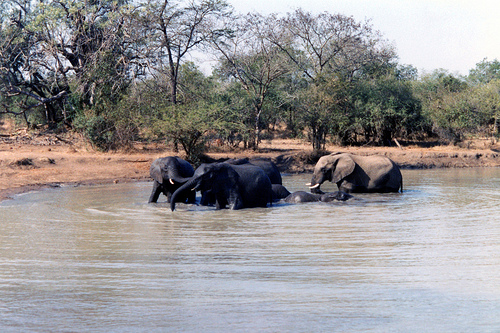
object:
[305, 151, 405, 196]
elephant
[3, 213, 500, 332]
water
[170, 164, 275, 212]
elephant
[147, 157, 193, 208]
elephant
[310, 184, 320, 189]
tusks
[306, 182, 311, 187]
tusks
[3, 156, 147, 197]
ground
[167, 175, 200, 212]
trunk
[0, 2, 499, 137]
trees